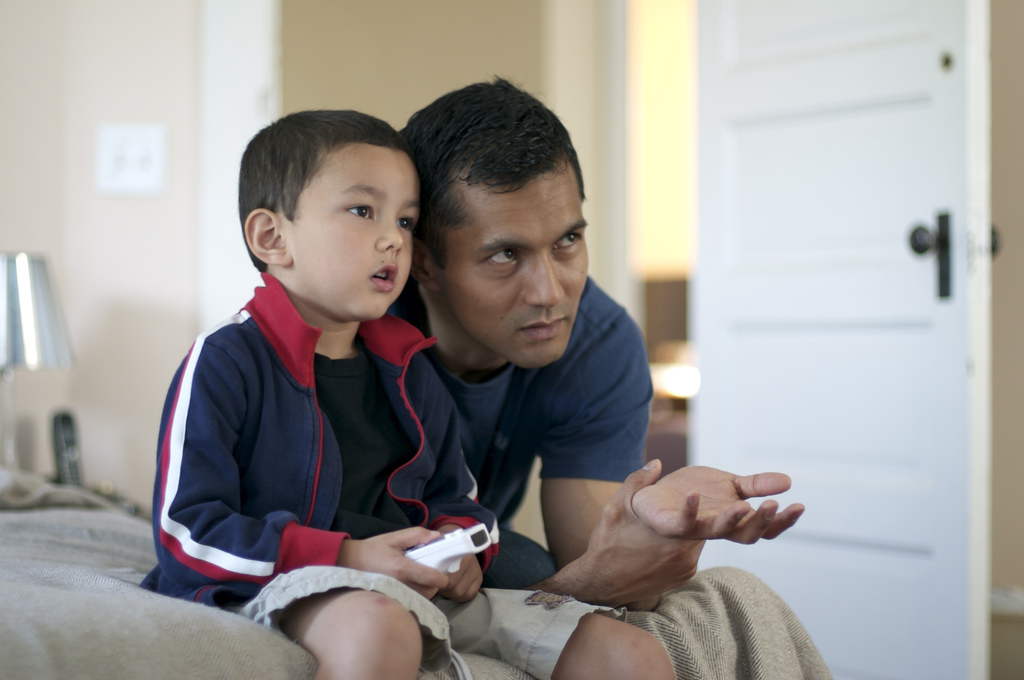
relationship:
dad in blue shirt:
[400, 77, 805, 609] [378, 276, 654, 523]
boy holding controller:
[136, 104, 690, 679] [405, 523, 492, 575]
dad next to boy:
[384, 48, 814, 630] [136, 104, 690, 679]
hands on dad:
[578, 461, 713, 628] [384, 48, 814, 630]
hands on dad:
[521, 458, 805, 611] [384, 48, 814, 630]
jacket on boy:
[133, 277, 522, 623] [136, 104, 690, 679]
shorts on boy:
[220, 530, 644, 678] [136, 104, 690, 679]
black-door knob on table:
[911, 227, 931, 253] [49, 474, 205, 539]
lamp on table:
[2, 234, 82, 468] [36, 472, 158, 522]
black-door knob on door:
[911, 227, 931, 253] [694, 3, 990, 675]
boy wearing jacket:
[136, 104, 690, 679] [133, 277, 522, 623]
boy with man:
[136, 104, 690, 679] [373, 81, 806, 641]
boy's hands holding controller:
[328, 515, 491, 617] [405, 523, 492, 575]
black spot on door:
[936, 44, 956, 70] [694, 3, 990, 675]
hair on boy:
[233, 111, 402, 233] [139, 107, 678, 680]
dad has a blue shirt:
[400, 77, 805, 609] [378, 279, 655, 506]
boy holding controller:
[139, 107, 678, 680] [406, 517, 495, 578]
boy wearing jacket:
[139, 107, 678, 680] [153, 271, 503, 596]